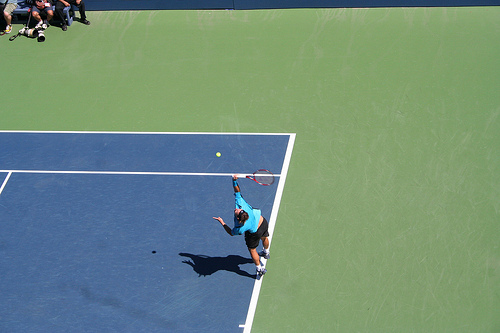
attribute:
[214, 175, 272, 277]
person — playing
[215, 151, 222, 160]
ball — green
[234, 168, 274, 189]
racket — red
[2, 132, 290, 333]
court — blue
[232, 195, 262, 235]
shirt — blue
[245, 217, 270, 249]
shorts — blue, black, brown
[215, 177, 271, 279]
man — playing, swinging, leaning, young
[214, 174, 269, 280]
player — swinging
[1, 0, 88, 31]
people — sitting, watching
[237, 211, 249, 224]
hair — brown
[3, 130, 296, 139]
line — white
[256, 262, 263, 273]
socks — black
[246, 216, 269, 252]
pants — black